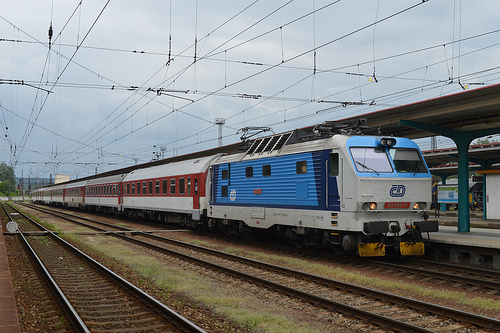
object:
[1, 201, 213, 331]
railroad track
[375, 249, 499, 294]
railroad track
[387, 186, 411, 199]
logo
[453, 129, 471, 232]
post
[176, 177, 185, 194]
window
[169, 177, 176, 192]
window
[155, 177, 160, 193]
window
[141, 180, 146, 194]
window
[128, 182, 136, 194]
window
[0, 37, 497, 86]
wires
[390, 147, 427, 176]
windshield pane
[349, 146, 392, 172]
windshield pane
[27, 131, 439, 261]
train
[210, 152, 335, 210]
paint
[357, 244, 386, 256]
mudflaps